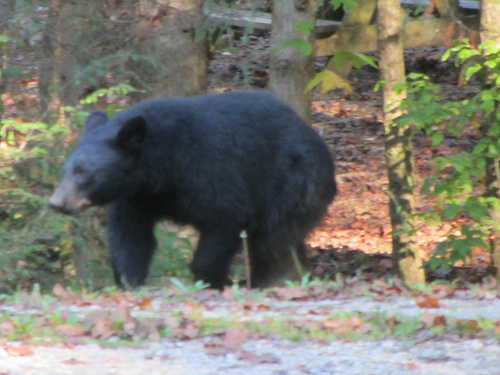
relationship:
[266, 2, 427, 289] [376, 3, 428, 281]
tree has trunk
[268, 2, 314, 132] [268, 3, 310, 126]
tree has trunk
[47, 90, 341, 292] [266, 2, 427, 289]
bear near tree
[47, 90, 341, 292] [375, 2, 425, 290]
bear near tree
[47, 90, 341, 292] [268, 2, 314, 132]
bear near tree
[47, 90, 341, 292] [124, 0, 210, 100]
bear near tree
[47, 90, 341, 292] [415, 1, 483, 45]
bear near tree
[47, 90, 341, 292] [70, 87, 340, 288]
bear has fur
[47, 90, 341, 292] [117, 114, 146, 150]
bear has ear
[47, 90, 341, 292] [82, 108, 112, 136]
bear has ear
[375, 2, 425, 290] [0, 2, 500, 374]
tree in woods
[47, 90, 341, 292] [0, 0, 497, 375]
bear on ground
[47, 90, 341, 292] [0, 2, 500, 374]
bear in woods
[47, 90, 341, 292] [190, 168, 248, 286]
bear on leg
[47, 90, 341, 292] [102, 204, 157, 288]
bear on leg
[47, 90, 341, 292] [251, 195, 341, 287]
bear on leg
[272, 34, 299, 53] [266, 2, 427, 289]
leaf on tree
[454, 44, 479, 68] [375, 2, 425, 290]
leaf on tree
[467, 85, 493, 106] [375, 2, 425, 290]
leaf on tree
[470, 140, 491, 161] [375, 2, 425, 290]
leaf on tree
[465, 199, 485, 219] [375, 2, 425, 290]
leaf on tree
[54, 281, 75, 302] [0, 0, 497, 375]
leaf on ground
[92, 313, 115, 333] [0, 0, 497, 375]
leaf on ground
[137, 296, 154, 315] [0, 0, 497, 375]
leaf on ground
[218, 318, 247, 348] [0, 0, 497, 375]
leaf on ground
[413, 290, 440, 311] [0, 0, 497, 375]
leaf on ground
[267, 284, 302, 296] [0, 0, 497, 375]
leaf on ground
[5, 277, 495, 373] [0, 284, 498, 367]
road with dead leaves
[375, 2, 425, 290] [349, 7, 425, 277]
tree has trunk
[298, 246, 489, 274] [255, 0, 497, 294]
shadow of leaves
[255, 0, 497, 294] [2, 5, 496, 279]
leaves in forest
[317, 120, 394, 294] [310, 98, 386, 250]
leaves on floor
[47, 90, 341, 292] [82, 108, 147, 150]
bear has ears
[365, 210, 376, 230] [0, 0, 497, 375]
leaf on ground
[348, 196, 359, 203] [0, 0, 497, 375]
leaf on ground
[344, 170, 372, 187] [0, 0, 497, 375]
leaf on ground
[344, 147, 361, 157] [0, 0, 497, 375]
leaf on ground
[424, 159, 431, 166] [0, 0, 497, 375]
leaf on ground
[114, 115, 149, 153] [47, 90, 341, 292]
ear of bear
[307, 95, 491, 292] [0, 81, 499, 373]
brown leaves on ground